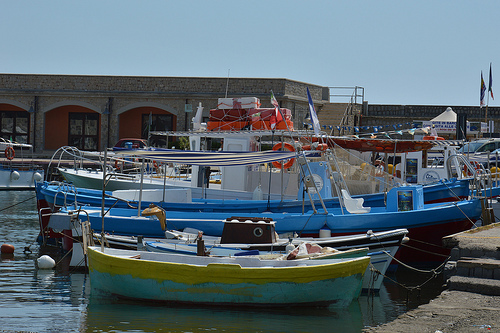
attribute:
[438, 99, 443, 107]
cones — orange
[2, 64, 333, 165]
building — brick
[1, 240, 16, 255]
buoy — red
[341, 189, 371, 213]
boat seat — white, plastic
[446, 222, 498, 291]
walkway — concrete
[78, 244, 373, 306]
boat — blue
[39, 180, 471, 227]
boat — blue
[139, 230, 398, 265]
boat — blue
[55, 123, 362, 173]
boat — blue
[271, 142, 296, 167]
life preserver — orange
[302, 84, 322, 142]
flag — blue and white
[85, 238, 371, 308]
small boat — blue, yellow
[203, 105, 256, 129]
cone — orange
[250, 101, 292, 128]
cone — orange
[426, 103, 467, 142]
tent — white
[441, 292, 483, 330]
stones — old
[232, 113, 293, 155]
cone — orange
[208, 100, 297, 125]
cones — orange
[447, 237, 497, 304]
stairs — stone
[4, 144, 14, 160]
life buoy — red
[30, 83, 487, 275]
boat — blue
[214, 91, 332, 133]
cones — orange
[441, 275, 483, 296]
stair — one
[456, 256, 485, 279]
stair — one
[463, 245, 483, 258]
stair — one